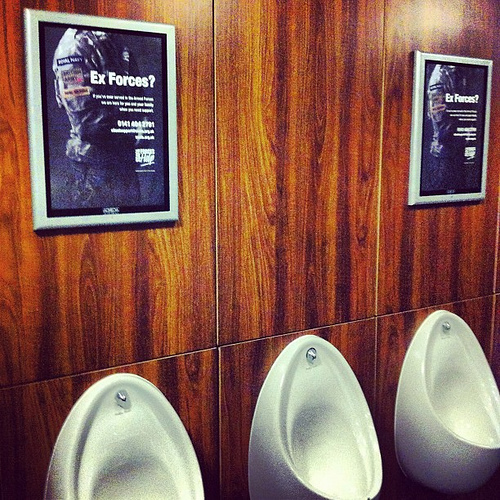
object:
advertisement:
[20, 7, 180, 233]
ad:
[407, 48, 495, 206]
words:
[108, 70, 150, 90]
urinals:
[40, 370, 205, 500]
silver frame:
[404, 47, 494, 210]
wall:
[0, 0, 500, 500]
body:
[52, 148, 143, 208]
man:
[51, 24, 145, 210]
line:
[214, 344, 224, 500]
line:
[209, 0, 221, 350]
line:
[373, 0, 388, 320]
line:
[0, 293, 500, 392]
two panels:
[0, 0, 223, 500]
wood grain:
[66, 232, 126, 380]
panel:
[374, 0, 500, 316]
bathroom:
[0, 0, 500, 500]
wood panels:
[0, 345, 223, 500]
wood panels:
[375, 0, 499, 317]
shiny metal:
[440, 322, 450, 331]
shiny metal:
[306, 347, 318, 364]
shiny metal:
[115, 389, 128, 403]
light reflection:
[386, 0, 476, 45]